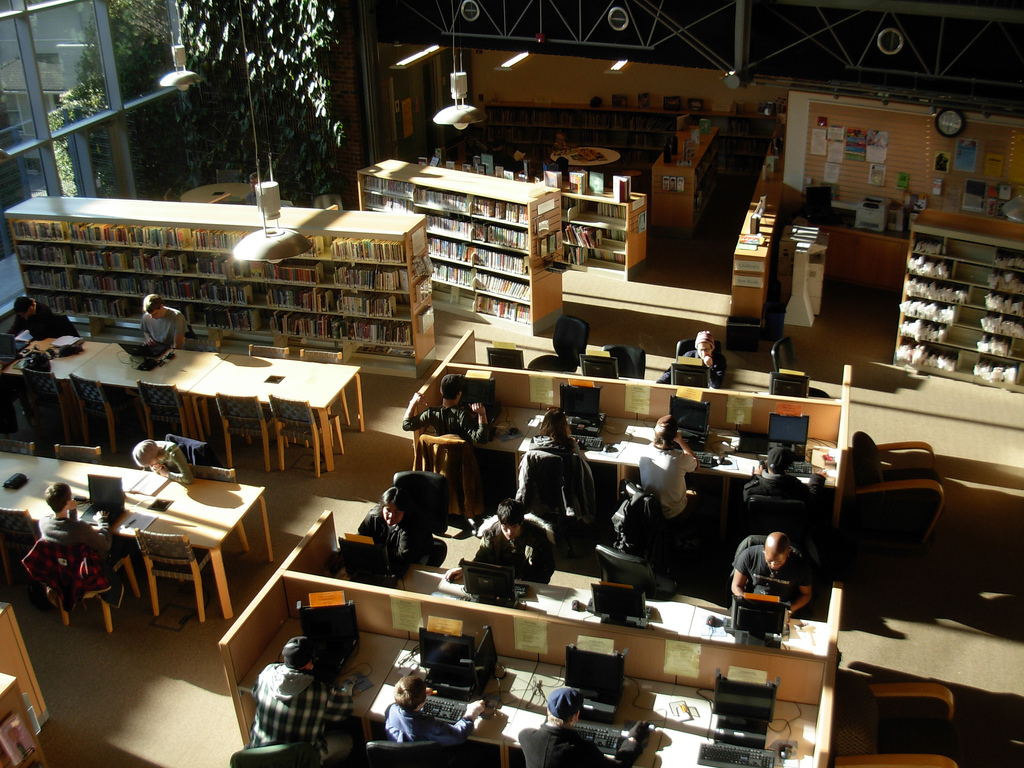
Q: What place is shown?
A: It is a library.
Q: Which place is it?
A: It is a library.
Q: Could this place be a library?
A: Yes, it is a library.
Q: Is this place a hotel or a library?
A: It is a library.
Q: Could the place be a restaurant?
A: No, it is a library.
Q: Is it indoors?
A: Yes, it is indoors.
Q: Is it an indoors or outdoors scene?
A: It is indoors.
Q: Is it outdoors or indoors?
A: It is indoors.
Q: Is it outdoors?
A: No, it is indoors.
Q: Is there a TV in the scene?
A: No, there are no televisions.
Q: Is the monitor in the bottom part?
A: Yes, the monitor is in the bottom of the image.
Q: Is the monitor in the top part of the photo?
A: No, the monitor is in the bottom of the image.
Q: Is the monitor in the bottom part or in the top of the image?
A: The monitor is in the bottom of the image.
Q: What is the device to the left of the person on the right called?
A: The device is a monitor.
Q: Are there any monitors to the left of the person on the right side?
A: Yes, there is a monitor to the left of the person.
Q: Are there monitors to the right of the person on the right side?
A: No, the monitor is to the left of the person.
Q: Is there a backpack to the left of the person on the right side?
A: No, there is a monitor to the left of the person.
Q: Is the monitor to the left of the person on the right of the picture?
A: Yes, the monitor is to the left of the person.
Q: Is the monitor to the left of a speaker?
A: No, the monitor is to the left of the person.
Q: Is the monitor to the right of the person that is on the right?
A: No, the monitor is to the left of the person.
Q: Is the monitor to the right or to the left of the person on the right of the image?
A: The monitor is to the left of the person.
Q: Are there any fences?
A: No, there are no fences.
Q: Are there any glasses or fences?
A: No, there are no fences or glasses.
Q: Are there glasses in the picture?
A: No, there are no glasses.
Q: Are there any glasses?
A: No, there are no glasses.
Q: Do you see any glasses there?
A: No, there are no glasses.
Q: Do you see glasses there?
A: No, there are no glasses.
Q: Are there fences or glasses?
A: No, there are no glasses or fences.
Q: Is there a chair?
A: Yes, there is a chair.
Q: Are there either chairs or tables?
A: Yes, there is a chair.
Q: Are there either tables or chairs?
A: Yes, there is a chair.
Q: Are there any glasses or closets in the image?
A: No, there are no glasses or closets.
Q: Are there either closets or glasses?
A: No, there are no glasses or closets.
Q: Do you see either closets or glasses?
A: No, there are no glasses or closets.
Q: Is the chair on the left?
A: Yes, the chair is on the left of the image.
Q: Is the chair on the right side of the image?
A: No, the chair is on the left of the image.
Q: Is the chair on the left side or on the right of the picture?
A: The chair is on the left of the image.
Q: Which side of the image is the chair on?
A: The chair is on the left of the image.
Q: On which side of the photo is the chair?
A: The chair is on the left of the image.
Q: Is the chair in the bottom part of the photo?
A: Yes, the chair is in the bottom of the image.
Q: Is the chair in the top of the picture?
A: No, the chair is in the bottom of the image.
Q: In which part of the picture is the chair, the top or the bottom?
A: The chair is in the bottom of the image.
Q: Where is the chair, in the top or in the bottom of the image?
A: The chair is in the bottom of the image.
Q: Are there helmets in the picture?
A: No, there are no helmets.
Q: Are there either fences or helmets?
A: No, there are no helmets or fences.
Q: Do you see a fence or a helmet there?
A: No, there are no helmets or fences.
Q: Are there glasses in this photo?
A: No, there are no glasses.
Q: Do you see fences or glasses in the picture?
A: No, there are no glasses or fences.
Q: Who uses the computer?
A: The man uses the computer.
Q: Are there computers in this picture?
A: Yes, there is a computer.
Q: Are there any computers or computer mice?
A: Yes, there is a computer.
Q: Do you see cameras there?
A: No, there are no cameras.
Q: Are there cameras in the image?
A: No, there are no cameras.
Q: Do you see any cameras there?
A: No, there are no cameras.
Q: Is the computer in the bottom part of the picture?
A: Yes, the computer is in the bottom of the image.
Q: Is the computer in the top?
A: No, the computer is in the bottom of the image.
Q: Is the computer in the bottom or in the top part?
A: The computer is in the bottom of the image.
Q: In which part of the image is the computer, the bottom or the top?
A: The computer is in the bottom of the image.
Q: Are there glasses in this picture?
A: No, there are no glasses.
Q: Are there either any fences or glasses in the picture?
A: No, there are no glasses or fences.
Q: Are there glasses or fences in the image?
A: No, there are no glasses or fences.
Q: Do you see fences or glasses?
A: No, there are no glasses or fences.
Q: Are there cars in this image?
A: No, there are no cars.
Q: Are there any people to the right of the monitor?
A: Yes, there is a person to the right of the monitor.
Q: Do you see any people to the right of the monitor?
A: Yes, there is a person to the right of the monitor.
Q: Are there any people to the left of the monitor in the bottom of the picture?
A: No, the person is to the right of the monitor.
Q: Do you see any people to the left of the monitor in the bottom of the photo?
A: No, the person is to the right of the monitor.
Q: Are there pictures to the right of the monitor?
A: No, there is a person to the right of the monitor.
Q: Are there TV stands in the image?
A: No, there are no TV stands.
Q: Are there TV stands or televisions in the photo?
A: No, there are no TV stands or televisions.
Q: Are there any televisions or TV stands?
A: No, there are no TV stands or televisions.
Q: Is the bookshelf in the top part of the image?
A: Yes, the bookshelf is in the top of the image.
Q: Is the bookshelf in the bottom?
A: No, the bookshelf is in the top of the image.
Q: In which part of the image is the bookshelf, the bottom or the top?
A: The bookshelf is in the top of the image.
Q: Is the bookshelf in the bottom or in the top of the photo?
A: The bookshelf is in the top of the image.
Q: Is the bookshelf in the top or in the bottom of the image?
A: The bookshelf is in the top of the image.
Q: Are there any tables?
A: Yes, there is a table.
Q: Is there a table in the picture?
A: Yes, there is a table.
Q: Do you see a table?
A: Yes, there is a table.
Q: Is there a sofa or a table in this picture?
A: Yes, there is a table.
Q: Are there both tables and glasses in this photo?
A: No, there is a table but no glasses.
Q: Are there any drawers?
A: No, there are no drawers.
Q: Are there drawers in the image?
A: No, there are no drawers.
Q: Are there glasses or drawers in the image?
A: No, there are no drawers or glasses.